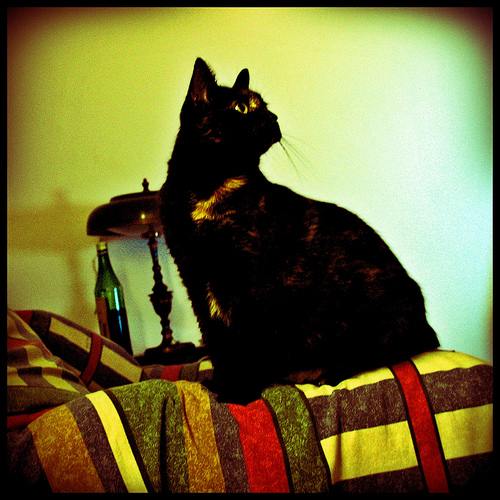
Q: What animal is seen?
A: Cat.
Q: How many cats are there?
A: 1.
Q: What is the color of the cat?
A: Black.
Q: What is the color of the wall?
A: White.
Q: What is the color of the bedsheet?
A: Yellow and red.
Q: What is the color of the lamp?
A: Brown.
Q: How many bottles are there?
A: One.